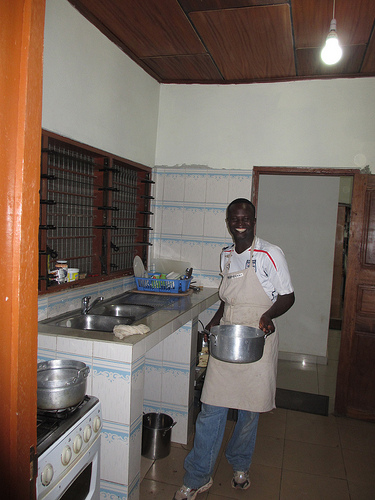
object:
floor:
[139, 408, 375, 499]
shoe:
[230, 465, 250, 490]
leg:
[185, 392, 229, 488]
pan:
[210, 324, 265, 363]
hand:
[259, 317, 275, 334]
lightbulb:
[320, 30, 343, 64]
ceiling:
[69, 0, 374, 82]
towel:
[113, 323, 151, 339]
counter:
[38, 286, 220, 499]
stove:
[37, 394, 102, 500]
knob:
[74, 434, 83, 454]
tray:
[133, 289, 193, 297]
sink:
[67, 315, 131, 329]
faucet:
[81, 296, 104, 314]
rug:
[145, 446, 189, 486]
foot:
[230, 471, 250, 489]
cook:
[172, 198, 295, 500]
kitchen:
[0, 0, 375, 500]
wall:
[160, 77, 375, 384]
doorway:
[257, 170, 357, 415]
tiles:
[184, 170, 206, 203]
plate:
[133, 254, 145, 282]